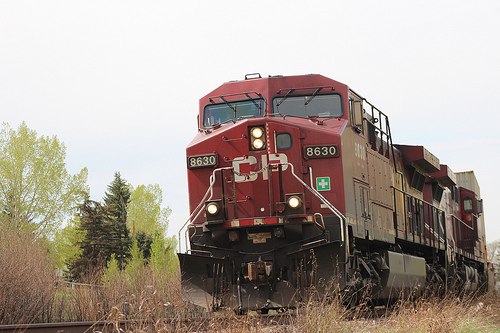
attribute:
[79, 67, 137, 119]
clouds — white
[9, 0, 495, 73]
sky — blue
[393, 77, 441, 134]
clouds — white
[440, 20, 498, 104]
sky — blue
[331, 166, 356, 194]
train — red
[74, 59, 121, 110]
sky — blue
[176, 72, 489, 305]
train — red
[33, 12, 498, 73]
skies — overcast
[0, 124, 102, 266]
tree — large, light green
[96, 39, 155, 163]
clouds — white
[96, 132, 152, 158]
sky — blue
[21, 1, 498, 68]
sky — blue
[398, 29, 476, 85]
sky — blue 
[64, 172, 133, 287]
tree — large, dark green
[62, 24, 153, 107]
clouds — white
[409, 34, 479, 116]
clouds — white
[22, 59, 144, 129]
sky — blue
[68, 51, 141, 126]
clouds — white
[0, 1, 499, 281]
clouds — white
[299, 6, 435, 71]
cloud — white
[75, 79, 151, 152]
clound — white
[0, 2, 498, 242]
sky — blue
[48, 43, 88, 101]
cloud — white